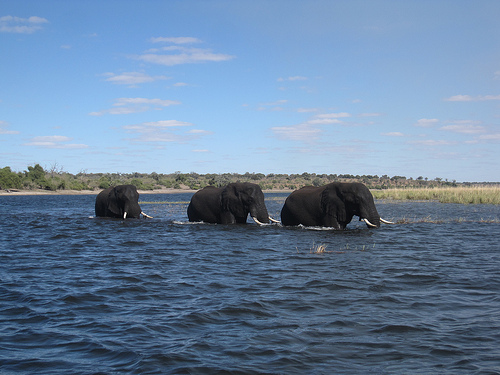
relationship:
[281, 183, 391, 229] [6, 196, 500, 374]
elephant in water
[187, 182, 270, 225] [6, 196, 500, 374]
elephant in water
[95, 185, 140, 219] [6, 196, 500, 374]
elephant in water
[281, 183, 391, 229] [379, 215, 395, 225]
elephant has tusk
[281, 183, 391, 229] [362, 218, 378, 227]
elephant has tusk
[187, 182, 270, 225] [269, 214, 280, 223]
elephant has tusk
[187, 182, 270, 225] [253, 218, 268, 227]
elephant has tusk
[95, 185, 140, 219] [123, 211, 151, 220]
elephant has tusks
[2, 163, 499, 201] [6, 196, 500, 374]
vegetation behind water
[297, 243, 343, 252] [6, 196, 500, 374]
grass in water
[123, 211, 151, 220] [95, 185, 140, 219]
tusks on elephant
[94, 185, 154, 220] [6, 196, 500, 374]
elephant traveling in water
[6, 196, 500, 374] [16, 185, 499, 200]
water near shore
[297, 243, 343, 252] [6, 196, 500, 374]
grass growing in water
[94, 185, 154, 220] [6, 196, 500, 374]
elephant are crossing river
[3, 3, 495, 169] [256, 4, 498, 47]
sky nt cloudless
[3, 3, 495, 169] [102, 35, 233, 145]
sky has clouds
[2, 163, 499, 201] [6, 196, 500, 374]
vegetation by water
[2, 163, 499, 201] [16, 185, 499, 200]
vegetation by shore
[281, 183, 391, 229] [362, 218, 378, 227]
elephant has left tusk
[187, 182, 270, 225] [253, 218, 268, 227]
elephant has left tusk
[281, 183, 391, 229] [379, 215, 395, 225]
elephant has right tusk